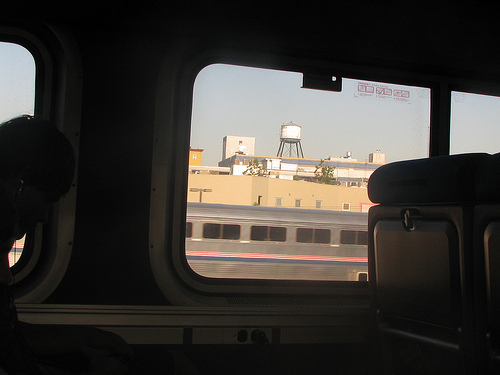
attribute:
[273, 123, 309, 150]
water tower — white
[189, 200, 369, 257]
train — Silver 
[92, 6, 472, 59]
train — moving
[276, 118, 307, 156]
water tower — white, round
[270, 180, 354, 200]
building — orange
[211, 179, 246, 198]
building — orange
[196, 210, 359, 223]
train car — silver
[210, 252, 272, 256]
stripe — red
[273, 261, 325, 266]
stripe — blue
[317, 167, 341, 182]
bush — large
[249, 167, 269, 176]
bush — large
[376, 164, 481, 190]
seat — black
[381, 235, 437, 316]
tray — upright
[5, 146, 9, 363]
person — looking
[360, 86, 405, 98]
instructions — red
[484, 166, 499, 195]
seat — black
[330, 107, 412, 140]
sky — blue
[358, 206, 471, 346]
tray — folds down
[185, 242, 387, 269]
stripes — red, blue 